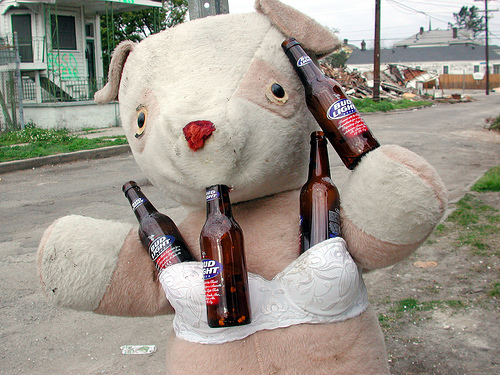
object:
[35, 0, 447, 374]
animal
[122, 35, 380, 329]
bottles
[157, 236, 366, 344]
bra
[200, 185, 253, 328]
bottle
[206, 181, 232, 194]
mouth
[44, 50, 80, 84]
graffiti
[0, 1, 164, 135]
house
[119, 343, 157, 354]
litter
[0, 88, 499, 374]
ground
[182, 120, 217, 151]
nose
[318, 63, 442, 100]
junk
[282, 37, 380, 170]
bottle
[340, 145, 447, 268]
hand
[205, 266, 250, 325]
stuff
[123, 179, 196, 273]
bottle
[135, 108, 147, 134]
eye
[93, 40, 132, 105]
ear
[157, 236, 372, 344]
pattern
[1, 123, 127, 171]
grass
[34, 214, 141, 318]
paws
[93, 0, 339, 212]
head